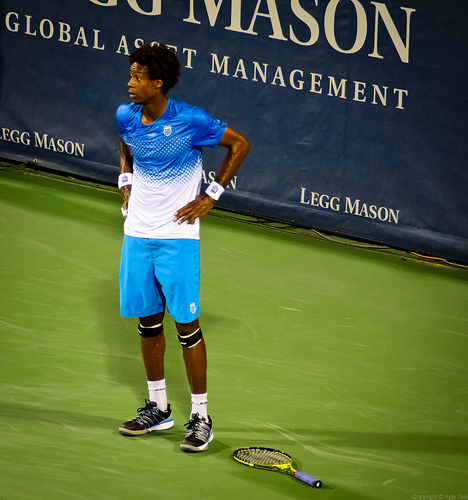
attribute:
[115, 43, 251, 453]
man — player, tennis player, playing, black, angry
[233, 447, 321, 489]
racket — tennis, yellow, black, blue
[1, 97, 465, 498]
court — tennis, green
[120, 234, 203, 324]
shorts — blue, tennnis, light blue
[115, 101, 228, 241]
shirt — blue, white, tennis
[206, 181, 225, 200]
wristband — white, blue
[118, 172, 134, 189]
wristband — white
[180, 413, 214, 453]
shoe — tennis, black, blue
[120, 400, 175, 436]
shoe — tennis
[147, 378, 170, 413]
sock — white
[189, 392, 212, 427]
sock — white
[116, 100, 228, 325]
outfit — tennis, light blue, white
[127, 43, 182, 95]
hair — black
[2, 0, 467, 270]
advertisement — blue, legg mason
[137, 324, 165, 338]
knee band — black, white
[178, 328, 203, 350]
knee band — black, white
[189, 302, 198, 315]
logo — white